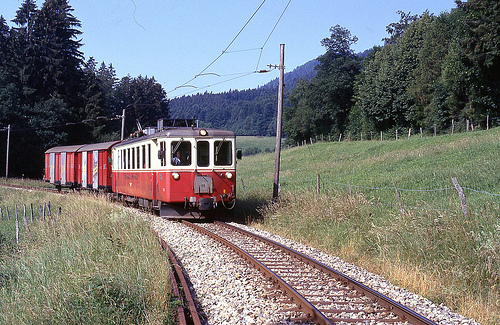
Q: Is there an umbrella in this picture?
A: No, there are no umbrellas.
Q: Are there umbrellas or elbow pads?
A: No, there are no umbrellas or elbow pads.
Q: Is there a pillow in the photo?
A: No, there are no pillows.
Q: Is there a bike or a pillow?
A: No, there are no pillows or bikes.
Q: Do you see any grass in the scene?
A: Yes, there is grass.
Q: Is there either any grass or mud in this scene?
A: Yes, there is grass.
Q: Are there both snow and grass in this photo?
A: No, there is grass but no snow.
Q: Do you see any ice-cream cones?
A: No, there are no ice-cream cones.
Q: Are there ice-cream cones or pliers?
A: No, there are no ice-cream cones or pliers.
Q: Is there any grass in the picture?
A: Yes, there is grass.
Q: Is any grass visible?
A: Yes, there is grass.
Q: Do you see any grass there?
A: Yes, there is grass.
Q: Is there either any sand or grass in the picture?
A: Yes, there is grass.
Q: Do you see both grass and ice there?
A: No, there is grass but no ice.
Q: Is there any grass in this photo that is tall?
A: Yes, there is tall grass.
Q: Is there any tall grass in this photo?
A: Yes, there is tall grass.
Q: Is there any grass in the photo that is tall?
A: Yes, there is grass that is tall.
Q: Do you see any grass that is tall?
A: Yes, there is grass that is tall.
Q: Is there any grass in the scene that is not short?
A: Yes, there is tall grass.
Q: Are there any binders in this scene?
A: No, there are no binders.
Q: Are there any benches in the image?
A: No, there are no benches.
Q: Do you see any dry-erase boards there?
A: No, there are no dry-erase boards.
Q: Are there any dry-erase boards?
A: No, there are no dry-erase boards.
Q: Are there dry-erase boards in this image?
A: No, there are no dry-erase boards.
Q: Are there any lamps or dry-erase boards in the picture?
A: No, there are no dry-erase boards or lamps.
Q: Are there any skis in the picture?
A: No, there are no skis.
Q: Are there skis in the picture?
A: No, there are no skis.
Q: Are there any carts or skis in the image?
A: No, there are no skis or carts.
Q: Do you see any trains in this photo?
A: Yes, there is a train.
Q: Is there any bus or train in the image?
A: Yes, there is a train.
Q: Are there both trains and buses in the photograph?
A: No, there is a train but no buses.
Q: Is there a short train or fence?
A: Yes, there is a short train.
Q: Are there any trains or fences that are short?
A: Yes, the train is short.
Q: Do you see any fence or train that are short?
A: Yes, the train is short.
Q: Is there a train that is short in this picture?
A: Yes, there is a short train.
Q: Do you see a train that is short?
A: Yes, there is a train that is short.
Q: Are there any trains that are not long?
A: Yes, there is a short train.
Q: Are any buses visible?
A: No, there are no buses.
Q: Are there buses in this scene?
A: No, there are no buses.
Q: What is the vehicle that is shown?
A: The vehicle is a train.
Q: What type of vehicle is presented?
A: The vehicle is a train.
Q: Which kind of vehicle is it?
A: The vehicle is a train.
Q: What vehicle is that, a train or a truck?
A: This is a train.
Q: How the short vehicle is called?
A: The vehicle is a train.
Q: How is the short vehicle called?
A: The vehicle is a train.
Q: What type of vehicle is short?
A: The vehicle is a train.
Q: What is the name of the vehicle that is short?
A: The vehicle is a train.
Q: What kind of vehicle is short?
A: The vehicle is a train.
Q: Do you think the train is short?
A: Yes, the train is short.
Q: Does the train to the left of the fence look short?
A: Yes, the train is short.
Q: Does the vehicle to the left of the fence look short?
A: Yes, the train is short.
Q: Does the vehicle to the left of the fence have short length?
A: Yes, the train is short.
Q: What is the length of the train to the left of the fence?
A: The train is short.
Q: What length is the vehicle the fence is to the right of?
A: The train is short.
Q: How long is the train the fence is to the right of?
A: The train is short.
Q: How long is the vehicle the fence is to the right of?
A: The train is short.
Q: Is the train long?
A: No, the train is short.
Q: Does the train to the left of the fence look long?
A: No, the train is short.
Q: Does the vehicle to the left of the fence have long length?
A: No, the train is short.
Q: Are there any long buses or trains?
A: No, there is a train but it is short.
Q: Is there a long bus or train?
A: No, there is a train but it is short.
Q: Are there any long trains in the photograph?
A: No, there is a train but it is short.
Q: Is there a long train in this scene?
A: No, there is a train but it is short.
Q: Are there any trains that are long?
A: No, there is a train but it is short.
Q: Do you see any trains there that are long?
A: No, there is a train but it is short.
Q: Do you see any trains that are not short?
A: No, there is a train but it is short.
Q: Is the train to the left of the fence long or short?
A: The train is short.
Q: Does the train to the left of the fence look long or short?
A: The train is short.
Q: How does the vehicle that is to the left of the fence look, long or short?
A: The train is short.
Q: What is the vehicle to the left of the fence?
A: The vehicle is a train.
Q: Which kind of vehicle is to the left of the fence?
A: The vehicle is a train.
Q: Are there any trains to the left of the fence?
A: Yes, there is a train to the left of the fence.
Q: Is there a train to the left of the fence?
A: Yes, there is a train to the left of the fence.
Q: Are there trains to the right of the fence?
A: No, the train is to the left of the fence.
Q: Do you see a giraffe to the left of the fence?
A: No, there is a train to the left of the fence.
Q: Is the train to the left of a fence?
A: Yes, the train is to the left of a fence.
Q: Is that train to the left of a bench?
A: No, the train is to the left of a fence.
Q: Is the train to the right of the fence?
A: No, the train is to the left of the fence.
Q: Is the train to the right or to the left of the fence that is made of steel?
A: The train is to the left of the fence.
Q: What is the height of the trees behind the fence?
A: The trees are tall.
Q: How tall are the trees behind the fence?
A: The trees are tall.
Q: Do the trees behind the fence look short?
A: No, the trees are tall.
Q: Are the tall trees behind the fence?
A: Yes, the trees are behind the fence.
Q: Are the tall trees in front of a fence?
A: No, the trees are behind a fence.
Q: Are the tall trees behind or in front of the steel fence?
A: The trees are behind the fence.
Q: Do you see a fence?
A: Yes, there is a fence.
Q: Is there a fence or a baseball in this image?
A: Yes, there is a fence.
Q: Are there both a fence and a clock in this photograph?
A: No, there is a fence but no clocks.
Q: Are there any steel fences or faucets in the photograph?
A: Yes, there is a steel fence.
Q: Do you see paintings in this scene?
A: No, there are no paintings.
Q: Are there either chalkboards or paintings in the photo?
A: No, there are no paintings or chalkboards.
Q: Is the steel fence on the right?
A: Yes, the fence is on the right of the image.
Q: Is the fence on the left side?
A: No, the fence is on the right of the image.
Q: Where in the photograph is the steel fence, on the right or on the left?
A: The fence is on the right of the image.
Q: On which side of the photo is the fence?
A: The fence is on the right of the image.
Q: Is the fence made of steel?
A: Yes, the fence is made of steel.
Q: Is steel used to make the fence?
A: Yes, the fence is made of steel.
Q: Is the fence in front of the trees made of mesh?
A: No, the fence is made of steel.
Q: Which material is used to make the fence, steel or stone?
A: The fence is made of steel.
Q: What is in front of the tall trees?
A: The fence is in front of the trees.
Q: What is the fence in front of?
A: The fence is in front of the trees.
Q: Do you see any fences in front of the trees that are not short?
A: Yes, there is a fence in front of the trees.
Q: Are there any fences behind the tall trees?
A: No, the fence is in front of the trees.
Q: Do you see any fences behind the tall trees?
A: No, the fence is in front of the trees.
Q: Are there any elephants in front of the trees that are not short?
A: No, there is a fence in front of the trees.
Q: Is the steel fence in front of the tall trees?
A: Yes, the fence is in front of the trees.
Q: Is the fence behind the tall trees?
A: No, the fence is in front of the trees.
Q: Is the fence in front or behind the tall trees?
A: The fence is in front of the trees.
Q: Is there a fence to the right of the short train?
A: Yes, there is a fence to the right of the train.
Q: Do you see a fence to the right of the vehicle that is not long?
A: Yes, there is a fence to the right of the train.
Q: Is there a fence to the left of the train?
A: No, the fence is to the right of the train.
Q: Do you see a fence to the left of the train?
A: No, the fence is to the right of the train.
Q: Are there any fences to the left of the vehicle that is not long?
A: No, the fence is to the right of the train.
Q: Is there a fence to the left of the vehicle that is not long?
A: No, the fence is to the right of the train.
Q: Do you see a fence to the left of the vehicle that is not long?
A: No, the fence is to the right of the train.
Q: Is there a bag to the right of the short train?
A: No, there is a fence to the right of the train.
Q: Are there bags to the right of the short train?
A: No, there is a fence to the right of the train.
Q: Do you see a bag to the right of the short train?
A: No, there is a fence to the right of the train.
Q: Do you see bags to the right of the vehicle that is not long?
A: No, there is a fence to the right of the train.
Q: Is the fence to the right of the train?
A: Yes, the fence is to the right of the train.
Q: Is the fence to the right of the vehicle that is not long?
A: Yes, the fence is to the right of the train.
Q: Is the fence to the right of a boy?
A: No, the fence is to the right of the train.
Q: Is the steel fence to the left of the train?
A: No, the fence is to the right of the train.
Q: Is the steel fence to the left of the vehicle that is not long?
A: No, the fence is to the right of the train.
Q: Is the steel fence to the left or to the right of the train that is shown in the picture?
A: The fence is to the right of the train.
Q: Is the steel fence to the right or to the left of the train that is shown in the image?
A: The fence is to the right of the train.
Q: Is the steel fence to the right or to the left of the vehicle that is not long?
A: The fence is to the right of the train.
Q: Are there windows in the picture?
A: Yes, there is a window.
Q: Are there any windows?
A: Yes, there is a window.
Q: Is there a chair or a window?
A: Yes, there is a window.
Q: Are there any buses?
A: No, there are no buses.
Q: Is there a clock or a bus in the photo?
A: No, there are no buses or clocks.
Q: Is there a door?
A: Yes, there is a door.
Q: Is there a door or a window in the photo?
A: Yes, there is a door.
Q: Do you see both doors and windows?
A: Yes, there are both a door and a window.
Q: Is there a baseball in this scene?
A: No, there are no baseballs.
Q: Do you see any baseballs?
A: No, there are no baseballs.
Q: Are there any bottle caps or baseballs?
A: No, there are no baseballs or bottle caps.